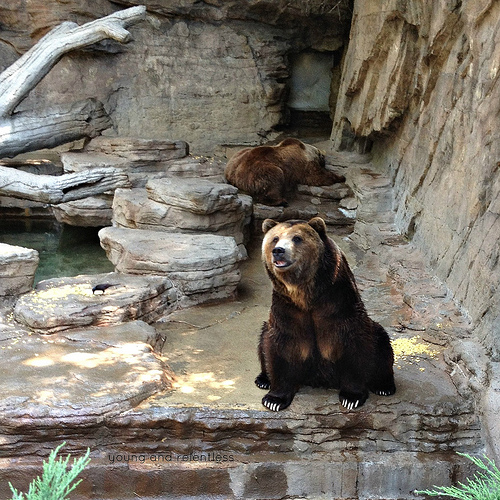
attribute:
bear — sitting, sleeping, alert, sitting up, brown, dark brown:
[245, 217, 398, 411]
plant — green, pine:
[8, 440, 92, 499]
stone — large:
[112, 177, 252, 263]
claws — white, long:
[341, 397, 363, 411]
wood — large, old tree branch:
[0, 4, 149, 204]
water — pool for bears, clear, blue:
[0, 217, 118, 285]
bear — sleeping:
[224, 137, 346, 205]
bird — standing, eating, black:
[91, 282, 121, 294]